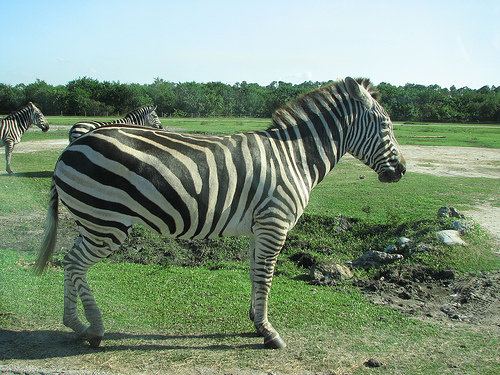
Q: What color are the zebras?
A: Black and white.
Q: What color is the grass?
A: Green.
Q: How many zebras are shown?
A: Three.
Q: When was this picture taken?
A: Daytime.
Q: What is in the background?
A: Trees.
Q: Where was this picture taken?
A: A field.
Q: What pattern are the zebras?
A: Striped.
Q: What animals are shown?
A: Zebras.